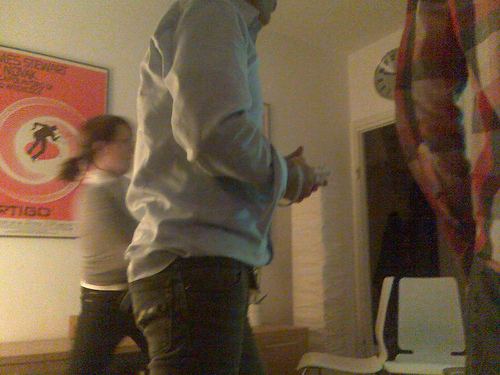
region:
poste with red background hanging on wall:
[4, 45, 122, 252]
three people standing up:
[70, 5, 499, 351]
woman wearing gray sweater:
[47, 115, 177, 365]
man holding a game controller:
[141, 5, 328, 355]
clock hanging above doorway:
[365, 49, 410, 100]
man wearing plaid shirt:
[385, 8, 485, 371]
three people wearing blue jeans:
[63, 12, 485, 374]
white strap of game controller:
[275, 158, 311, 210]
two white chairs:
[299, 260, 469, 374]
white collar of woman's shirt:
[80, 165, 133, 193]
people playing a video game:
[45, 6, 347, 357]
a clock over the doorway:
[363, 39, 440, 106]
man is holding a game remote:
[190, 2, 355, 234]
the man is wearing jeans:
[103, 205, 290, 372]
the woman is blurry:
[16, 90, 151, 342]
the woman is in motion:
[28, 95, 149, 349]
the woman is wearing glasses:
[7, 94, 137, 170]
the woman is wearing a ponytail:
[32, 91, 146, 191]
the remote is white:
[262, 134, 341, 219]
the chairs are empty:
[282, 251, 474, 369]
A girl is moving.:
[64, 112, 170, 361]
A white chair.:
[386, 265, 468, 370]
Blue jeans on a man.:
[116, 231, 277, 371]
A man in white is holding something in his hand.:
[87, 0, 349, 374]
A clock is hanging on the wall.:
[366, 30, 434, 116]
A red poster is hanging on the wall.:
[1, 46, 121, 249]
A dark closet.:
[338, 97, 461, 362]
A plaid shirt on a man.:
[358, 1, 495, 309]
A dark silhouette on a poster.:
[23, 110, 66, 166]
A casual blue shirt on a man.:
[111, 1, 290, 286]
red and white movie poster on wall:
[1, 38, 128, 275]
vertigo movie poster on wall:
[5, 45, 146, 259]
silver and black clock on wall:
[363, 38, 431, 119]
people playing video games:
[77, 0, 337, 360]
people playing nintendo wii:
[37, 1, 362, 353]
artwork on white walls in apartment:
[10, 21, 417, 308]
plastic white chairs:
[292, 266, 454, 373]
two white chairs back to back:
[287, 257, 489, 373]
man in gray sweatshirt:
[122, 7, 323, 283]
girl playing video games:
[57, 114, 179, 339]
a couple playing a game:
[51, 1, 326, 366]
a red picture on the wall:
[0, 50, 135, 240]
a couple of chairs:
[295, 270, 470, 365]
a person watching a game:
[386, 30, 491, 360]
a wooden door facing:
[345, 110, 366, 330]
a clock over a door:
[360, 45, 410, 100]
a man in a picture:
[20, 110, 65, 165]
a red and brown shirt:
[397, 35, 482, 270]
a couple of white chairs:
[294, 257, 484, 364]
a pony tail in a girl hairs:
[56, 115, 138, 186]